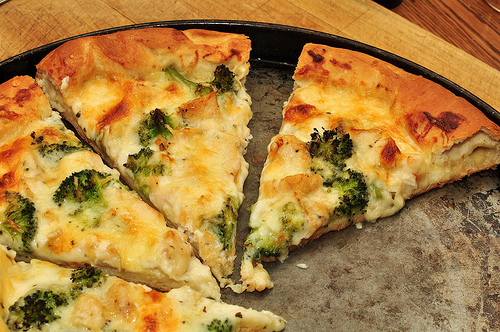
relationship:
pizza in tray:
[1, 28, 499, 331] [0, 20, 498, 331]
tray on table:
[0, 20, 498, 331] [1, 2, 499, 332]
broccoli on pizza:
[307, 128, 354, 166] [1, 28, 499, 331]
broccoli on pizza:
[327, 169, 370, 216] [1, 28, 499, 331]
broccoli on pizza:
[7, 288, 67, 331] [1, 28, 499, 331]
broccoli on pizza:
[55, 169, 114, 204] [1, 28, 499, 331]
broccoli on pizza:
[136, 109, 180, 145] [1, 28, 499, 331]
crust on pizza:
[59, 30, 233, 66] [1, 28, 499, 331]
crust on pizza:
[409, 83, 480, 135] [1, 28, 499, 331]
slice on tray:
[242, 42, 500, 283] [0, 20, 498, 331]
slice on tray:
[38, 28, 251, 276] [0, 20, 498, 331]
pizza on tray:
[1, 28, 499, 331] [0, 20, 498, 331]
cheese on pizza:
[173, 135, 241, 188] [1, 28, 499, 331]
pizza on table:
[1, 28, 499, 331] [1, 2, 499, 332]